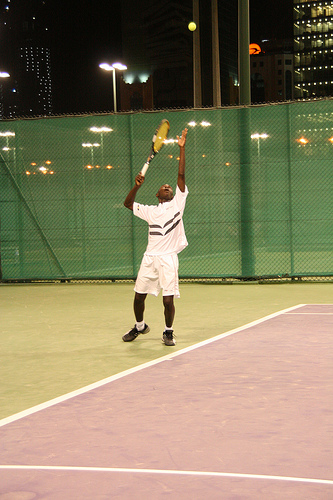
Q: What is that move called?
A: Serving.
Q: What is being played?
A: Tennis.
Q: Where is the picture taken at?
A: A tennis court.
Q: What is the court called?
A: Tennis court.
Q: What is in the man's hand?
A: Tennis racquet.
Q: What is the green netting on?
A: A fence.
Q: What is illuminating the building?
A: Lights.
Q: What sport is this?
A: Tennis.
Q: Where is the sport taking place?
A: Tennis court.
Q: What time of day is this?
A: Nighttime hours.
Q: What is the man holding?
A: Tennis racket.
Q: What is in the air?
A: Tennis ball.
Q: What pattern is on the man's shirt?
A: Stripes.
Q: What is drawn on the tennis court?
A: White lines.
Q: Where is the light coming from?
A: Tall street lamps.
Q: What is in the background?
A: City buildings.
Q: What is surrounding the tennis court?
A: Tall green net fence.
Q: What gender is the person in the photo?
A: Male.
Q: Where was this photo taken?
A: On a court.